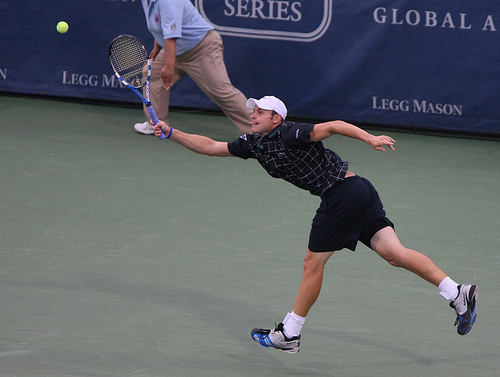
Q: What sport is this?
A: Tennis.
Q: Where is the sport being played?
A: Tennis court.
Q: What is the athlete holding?
A: Tennis racket.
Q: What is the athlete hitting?
A: Tennis ball.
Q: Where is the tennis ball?
A: In the air.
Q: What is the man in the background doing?
A: Running.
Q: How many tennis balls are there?
A: One.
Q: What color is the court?
A: Grey.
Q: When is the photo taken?
A: During the day.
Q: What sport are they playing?
A: Tennis.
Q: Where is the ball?
A: In the air.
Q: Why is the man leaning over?
A: To hit the ball.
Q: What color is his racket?
A: Blue.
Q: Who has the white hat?
A: The tennis player.